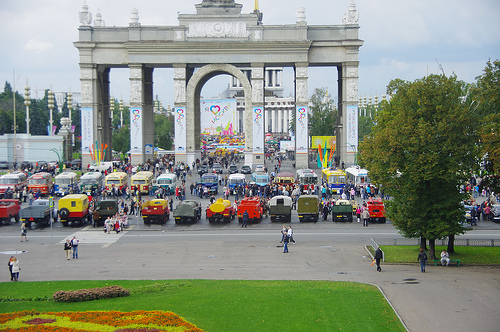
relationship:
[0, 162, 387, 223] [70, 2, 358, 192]
cars in front monument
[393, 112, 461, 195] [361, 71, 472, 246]
leaves on tree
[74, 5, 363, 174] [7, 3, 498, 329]
monument in city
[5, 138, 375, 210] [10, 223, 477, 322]
people on ground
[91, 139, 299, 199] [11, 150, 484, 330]
people walking park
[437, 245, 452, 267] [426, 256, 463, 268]
person sitting bench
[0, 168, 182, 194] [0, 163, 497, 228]
buses on parking lot